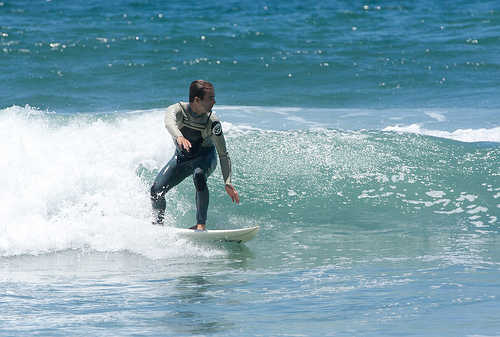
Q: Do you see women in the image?
A: No, there are no women.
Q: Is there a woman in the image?
A: No, there are no women.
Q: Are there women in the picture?
A: No, there are no women.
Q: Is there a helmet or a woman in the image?
A: No, there are no women or helmets.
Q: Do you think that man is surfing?
A: Yes, the man is surfing.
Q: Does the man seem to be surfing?
A: Yes, the man is surfing.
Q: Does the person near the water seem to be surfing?
A: Yes, the man is surfing.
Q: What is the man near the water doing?
A: The man is surfing.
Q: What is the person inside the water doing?
A: The man is surfing.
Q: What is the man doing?
A: The man is surfing.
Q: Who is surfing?
A: The man is surfing.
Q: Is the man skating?
A: No, the man is surfing.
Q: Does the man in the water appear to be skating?
A: No, the man is surfing.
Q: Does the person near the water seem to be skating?
A: No, the man is surfing.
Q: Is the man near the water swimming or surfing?
A: The man is surfing.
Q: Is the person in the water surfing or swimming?
A: The man is surfing.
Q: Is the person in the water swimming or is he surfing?
A: The man is surfing.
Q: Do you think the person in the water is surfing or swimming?
A: The man is surfing.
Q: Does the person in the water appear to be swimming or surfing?
A: The man is surfing.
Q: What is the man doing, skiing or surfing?
A: The man is surfing.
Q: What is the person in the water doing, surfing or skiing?
A: The man is surfing.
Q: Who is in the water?
A: The man is in the water.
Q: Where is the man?
A: The man is in the water.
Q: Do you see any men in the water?
A: Yes, there is a man in the water.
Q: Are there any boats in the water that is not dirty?
A: No, there is a man in the water.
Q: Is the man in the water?
A: Yes, the man is in the water.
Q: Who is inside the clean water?
A: The man is inside the water.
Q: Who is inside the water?
A: The man is inside the water.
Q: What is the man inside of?
A: The man is inside the water.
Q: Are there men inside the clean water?
A: Yes, there is a man inside the water.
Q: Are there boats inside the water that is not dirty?
A: No, there is a man inside the water.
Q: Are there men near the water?
A: Yes, there is a man near the water.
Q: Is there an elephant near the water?
A: No, there is a man near the water.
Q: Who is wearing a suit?
A: The man is wearing a suit.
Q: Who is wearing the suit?
A: The man is wearing a suit.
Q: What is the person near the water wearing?
A: The man is wearing a suit.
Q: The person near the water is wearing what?
A: The man is wearing a suit.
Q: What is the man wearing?
A: The man is wearing a suit.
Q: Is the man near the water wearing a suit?
A: Yes, the man is wearing a suit.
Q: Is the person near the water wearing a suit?
A: Yes, the man is wearing a suit.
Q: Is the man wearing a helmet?
A: No, the man is wearing a suit.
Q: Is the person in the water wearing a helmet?
A: No, the man is wearing a suit.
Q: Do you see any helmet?
A: No, there are no helmets.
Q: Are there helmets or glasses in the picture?
A: No, there are no helmets or glasses.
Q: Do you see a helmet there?
A: No, there are no helmets.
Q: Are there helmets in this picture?
A: No, there are no helmets.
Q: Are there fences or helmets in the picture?
A: No, there are no helmets or fences.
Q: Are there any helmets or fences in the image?
A: No, there are no helmets or fences.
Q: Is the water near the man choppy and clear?
A: No, the water is clear but calm.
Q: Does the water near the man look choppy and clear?
A: No, the water is clear but calm.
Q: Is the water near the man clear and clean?
A: Yes, the water is clear and clean.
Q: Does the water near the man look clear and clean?
A: Yes, the water is clear and clean.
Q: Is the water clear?
A: Yes, the water is clear.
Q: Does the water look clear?
A: Yes, the water is clear.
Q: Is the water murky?
A: No, the water is clear.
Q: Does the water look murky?
A: No, the water is clear.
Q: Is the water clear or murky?
A: The water is clear.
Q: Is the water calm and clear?
A: Yes, the water is calm and clear.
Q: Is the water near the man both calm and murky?
A: No, the water is calm but clear.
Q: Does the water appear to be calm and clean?
A: Yes, the water is calm and clean.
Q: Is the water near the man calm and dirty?
A: No, the water is calm but clean.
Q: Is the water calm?
A: Yes, the water is calm.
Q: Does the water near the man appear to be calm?
A: Yes, the water is calm.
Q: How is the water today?
A: The water is calm.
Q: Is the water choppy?
A: No, the water is calm.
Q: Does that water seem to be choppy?
A: No, the water is calm.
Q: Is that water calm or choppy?
A: The water is calm.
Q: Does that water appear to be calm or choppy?
A: The water is calm.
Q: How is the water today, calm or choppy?
A: The water is calm.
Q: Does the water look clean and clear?
A: Yes, the water is clean and clear.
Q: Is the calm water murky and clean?
A: No, the water is clean but clear.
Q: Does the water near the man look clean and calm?
A: Yes, the water is clean and calm.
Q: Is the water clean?
A: Yes, the water is clean.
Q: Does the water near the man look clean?
A: Yes, the water is clean.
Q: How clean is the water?
A: The water is clean.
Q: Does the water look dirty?
A: No, the water is clean.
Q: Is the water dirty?
A: No, the water is clean.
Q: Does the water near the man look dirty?
A: No, the water is clean.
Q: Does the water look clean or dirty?
A: The water is clean.